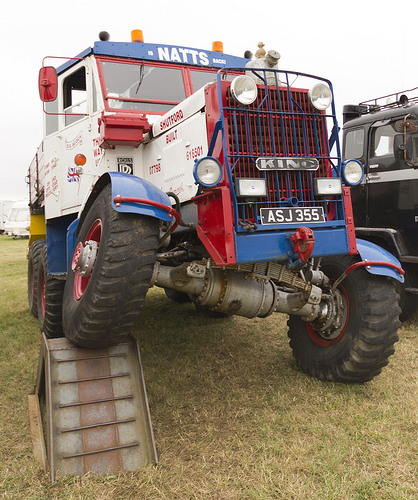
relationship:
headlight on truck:
[231, 76, 258, 105] [28, 29, 405, 387]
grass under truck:
[1, 233, 417, 499] [28, 29, 405, 387]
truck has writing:
[28, 29, 405, 387] [156, 46, 211, 67]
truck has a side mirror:
[28, 29, 405, 387] [39, 66, 57, 102]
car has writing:
[343, 104, 418, 290] [415, 214, 418, 223]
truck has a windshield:
[28, 29, 405, 387] [96, 55, 245, 116]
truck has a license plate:
[28, 29, 405, 387] [259, 206, 327, 225]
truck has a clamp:
[28, 29, 405, 387] [290, 226, 314, 259]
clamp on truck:
[290, 226, 314, 259] [28, 29, 405, 387]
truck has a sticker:
[28, 29, 405, 387] [159, 110, 184, 131]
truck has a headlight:
[28, 29, 405, 387] [195, 159, 223, 186]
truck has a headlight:
[28, 29, 405, 387] [231, 76, 258, 105]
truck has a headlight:
[28, 29, 405, 387] [309, 82, 333, 110]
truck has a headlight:
[28, 29, 405, 387] [344, 160, 363, 187]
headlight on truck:
[195, 159, 223, 186] [28, 29, 405, 387]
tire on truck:
[62, 181, 159, 351] [28, 29, 405, 387]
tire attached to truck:
[288, 253, 402, 389] [28, 29, 405, 387]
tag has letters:
[259, 206, 327, 225] [265, 209, 320, 221]